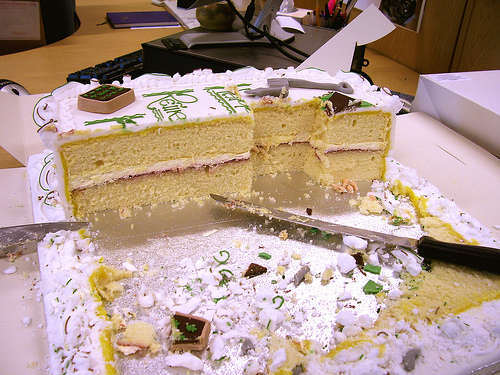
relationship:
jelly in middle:
[98, 167, 187, 183] [89, 161, 264, 177]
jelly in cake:
[98, 167, 187, 183] [26, 102, 399, 226]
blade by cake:
[224, 197, 382, 251] [26, 102, 399, 226]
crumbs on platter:
[169, 260, 327, 335] [44, 246, 436, 351]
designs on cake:
[149, 79, 217, 104] [26, 102, 399, 226]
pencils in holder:
[318, 5, 354, 19] [310, 11, 378, 65]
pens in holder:
[312, 6, 330, 22] [310, 11, 378, 65]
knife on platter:
[257, 199, 499, 278] [19, 67, 500, 375]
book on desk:
[106, 10, 180, 28] [37, 6, 195, 60]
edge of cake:
[397, 170, 456, 232] [26, 102, 399, 226]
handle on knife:
[427, 230, 493, 261] [257, 199, 499, 278]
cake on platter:
[26, 102, 399, 226] [19, 67, 500, 375]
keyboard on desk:
[89, 52, 149, 77] [37, 6, 195, 60]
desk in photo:
[0, 0, 500, 375] [25, 2, 496, 354]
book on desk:
[129, 2, 164, 28] [0, 0, 500, 375]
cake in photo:
[26, 102, 399, 226] [25, 2, 496, 354]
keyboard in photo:
[89, 52, 149, 77] [25, 2, 496, 354]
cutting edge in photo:
[235, 209, 289, 228] [25, 2, 496, 354]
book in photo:
[129, 2, 164, 28] [25, 2, 496, 354]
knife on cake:
[257, 199, 499, 278] [26, 102, 399, 226]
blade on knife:
[224, 197, 382, 251] [257, 199, 499, 278]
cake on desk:
[26, 102, 399, 226] [0, 0, 500, 375]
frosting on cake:
[146, 80, 246, 117] [26, 102, 399, 226]